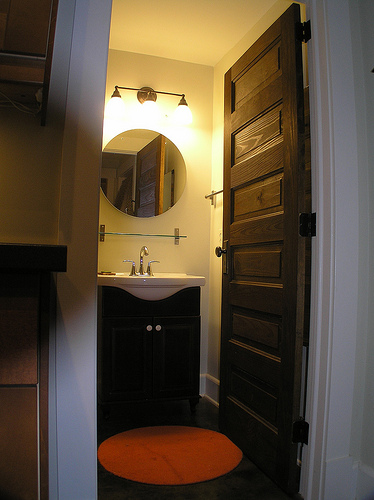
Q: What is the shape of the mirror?
A: Round.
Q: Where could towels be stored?
A: Under the sink.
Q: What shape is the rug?
A: Round.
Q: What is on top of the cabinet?
A: The sink.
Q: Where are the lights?
A: Above the mirror.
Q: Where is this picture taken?
A: A bathroom.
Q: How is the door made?
A: Of reclaimed wood.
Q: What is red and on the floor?
A: A rug.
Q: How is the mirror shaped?
A: Roundly.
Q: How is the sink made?
A: Of ceramic.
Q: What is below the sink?
A: Wooden cupboard.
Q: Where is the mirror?
A: On the wall.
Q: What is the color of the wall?
A: White.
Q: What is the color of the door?
A: Brown.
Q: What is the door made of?
A: Wood.